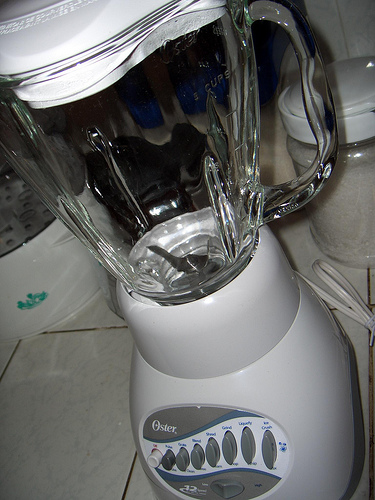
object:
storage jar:
[327, 180, 373, 236]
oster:
[145, 239, 210, 274]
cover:
[1, 0, 224, 110]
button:
[191, 443, 205, 469]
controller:
[136, 404, 294, 499]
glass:
[0, 0, 339, 307]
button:
[210, 478, 244, 498]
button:
[147, 449, 163, 469]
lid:
[0, 0, 227, 110]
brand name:
[152, 419, 178, 435]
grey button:
[261, 430, 277, 469]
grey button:
[241, 426, 256, 464]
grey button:
[222, 430, 237, 465]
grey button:
[191, 442, 205, 469]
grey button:
[175, 446, 188, 471]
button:
[261, 430, 276, 470]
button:
[206, 437, 220, 467]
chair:
[261, 429, 277, 470]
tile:
[2, 68, 373, 499]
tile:
[276, 1, 374, 96]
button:
[162, 448, 176, 470]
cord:
[292, 257, 375, 348]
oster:
[152, 420, 178, 435]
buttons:
[147, 425, 278, 473]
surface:
[3, 79, 375, 499]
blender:
[1, 2, 374, 499]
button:
[222, 431, 237, 465]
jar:
[0, 0, 339, 305]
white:
[0, 0, 365, 499]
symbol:
[152, 419, 178, 434]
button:
[138, 402, 294, 498]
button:
[240, 426, 256, 465]